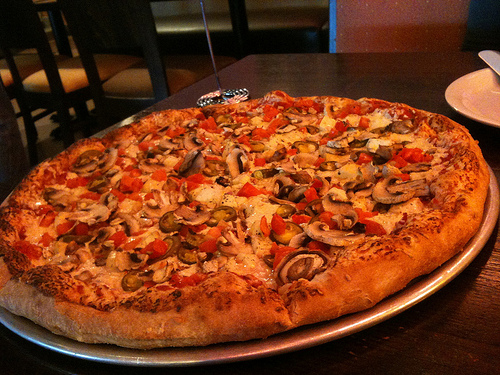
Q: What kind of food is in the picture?
A: Pizza.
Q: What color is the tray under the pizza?
A: Silver.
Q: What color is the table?
A: Brown.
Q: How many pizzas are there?
A: One.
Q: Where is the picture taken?
A: Pizza Restaurant.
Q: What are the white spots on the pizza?
A: Cheese.